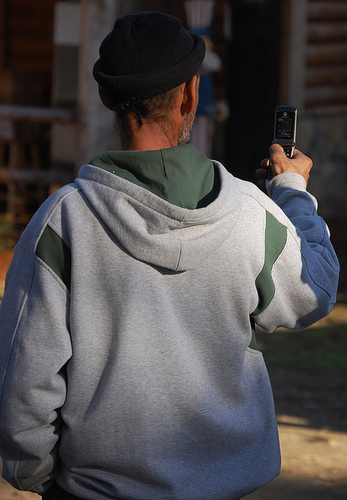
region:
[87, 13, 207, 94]
black hat on head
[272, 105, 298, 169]
cell phone in hand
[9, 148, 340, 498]
grey hooded sweat shirt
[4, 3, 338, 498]
man holding cell phone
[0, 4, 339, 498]
man wearing black hat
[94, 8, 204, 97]
black knit winter hat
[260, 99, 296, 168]
Man holding a cellphone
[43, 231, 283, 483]
man wearing a grey sweat shirt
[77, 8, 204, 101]
man wearing a black hat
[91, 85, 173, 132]
man with brown hair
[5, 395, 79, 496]
man hand in his pocket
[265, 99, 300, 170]
man looking a his cellphone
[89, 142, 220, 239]
green and gray hood on the sweater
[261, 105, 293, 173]
man making a phone call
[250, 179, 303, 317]
green stripe on the sweat shirt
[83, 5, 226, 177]
Head of a person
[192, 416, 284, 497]
Section of a sweater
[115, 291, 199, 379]
Section of a sweater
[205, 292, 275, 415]
Section of a sweater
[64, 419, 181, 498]
Section of a sweater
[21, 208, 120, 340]
Section of a sweater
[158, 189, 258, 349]
Section of a sweater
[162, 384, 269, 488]
Section of a sweater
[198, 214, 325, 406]
Section of a sweater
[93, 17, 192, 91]
A hat in the photo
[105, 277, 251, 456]
A gray hoodie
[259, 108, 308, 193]
A mobile phone in the hand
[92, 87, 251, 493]
A man in the photo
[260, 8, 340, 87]
Building in the background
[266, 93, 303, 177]
A man holding a cellphone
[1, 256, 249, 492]
A man with one hand in the pocket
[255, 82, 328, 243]
A man holding a cellphone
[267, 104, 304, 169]
A black and gray cellphone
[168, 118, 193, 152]
Beard on the man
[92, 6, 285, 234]
a man wearing a black beanie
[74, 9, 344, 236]
a man looking at phone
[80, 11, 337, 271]
a man looking at cell phone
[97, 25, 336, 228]
a man looking at flip phone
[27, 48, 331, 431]
a man wearing a jacket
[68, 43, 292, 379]
a man standing otuside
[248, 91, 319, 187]
a hand holding a cell phone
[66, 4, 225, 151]
a man wearing a blue beanie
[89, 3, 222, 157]
a bearded man wearing a blue beanie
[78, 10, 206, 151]
black hat on the man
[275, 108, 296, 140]
screen on the cell phone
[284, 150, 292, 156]
button on the cell phone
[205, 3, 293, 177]
door on the building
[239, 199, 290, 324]
stripe on the jacket